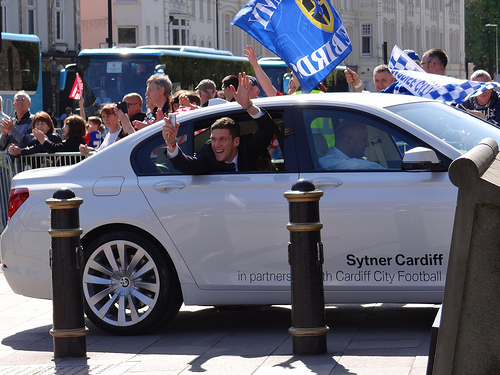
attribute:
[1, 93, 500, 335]
sedan — silver, four-doored, white, parked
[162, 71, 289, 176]
man — adult, waving, smiling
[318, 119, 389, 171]
man — driving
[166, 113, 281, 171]
jacket — black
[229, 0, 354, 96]
flag — blue, large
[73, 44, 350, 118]
bus — large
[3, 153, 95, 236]
fence — silver, metal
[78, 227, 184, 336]
tire — black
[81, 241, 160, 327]
rims — silver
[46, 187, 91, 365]
pole — brown, gold, black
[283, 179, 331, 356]
pole — brown, gold, black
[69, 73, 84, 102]
flag — red, white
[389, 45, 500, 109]
banner — blue, checkered, white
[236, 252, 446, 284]
writing — black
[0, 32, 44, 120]
bus — large, blue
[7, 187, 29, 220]
tail light — red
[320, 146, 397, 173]
shirt — white, long sleeved